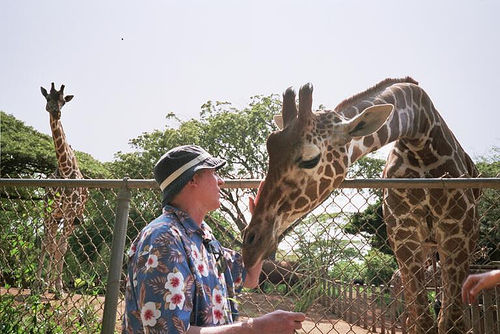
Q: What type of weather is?
A: It is clear.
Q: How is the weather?
A: It is clear.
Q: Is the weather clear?
A: Yes, it is clear.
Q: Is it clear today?
A: Yes, it is clear.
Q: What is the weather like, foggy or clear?
A: It is clear.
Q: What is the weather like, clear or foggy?
A: It is clear.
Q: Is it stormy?
A: No, it is clear.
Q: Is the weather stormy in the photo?
A: No, it is clear.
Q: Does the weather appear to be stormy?
A: No, it is clear.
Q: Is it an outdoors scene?
A: Yes, it is outdoors.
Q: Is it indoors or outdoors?
A: It is outdoors.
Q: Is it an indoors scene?
A: No, it is outdoors.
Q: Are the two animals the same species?
A: Yes, all the animals are giraffes.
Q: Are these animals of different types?
A: No, all the animals are giraffes.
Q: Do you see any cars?
A: No, there are no cars.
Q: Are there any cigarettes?
A: No, there are no cigarettes.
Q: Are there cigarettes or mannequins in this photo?
A: No, there are no cigarettes or mannequins.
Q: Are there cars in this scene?
A: No, there are no cars.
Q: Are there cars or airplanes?
A: No, there are no cars or airplanes.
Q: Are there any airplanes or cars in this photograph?
A: No, there are no cars or airplanes.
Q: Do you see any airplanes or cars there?
A: No, there are no cars or airplanes.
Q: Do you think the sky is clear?
A: Yes, the sky is clear.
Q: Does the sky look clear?
A: Yes, the sky is clear.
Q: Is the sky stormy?
A: No, the sky is clear.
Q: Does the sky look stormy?
A: No, the sky is clear.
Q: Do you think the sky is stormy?
A: No, the sky is clear.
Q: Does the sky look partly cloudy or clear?
A: The sky is clear.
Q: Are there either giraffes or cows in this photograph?
A: Yes, there is a giraffe.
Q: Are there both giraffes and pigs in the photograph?
A: No, there is a giraffe but no pigs.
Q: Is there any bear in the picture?
A: No, there are no bears.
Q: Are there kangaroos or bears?
A: No, there are no bears or kangaroos.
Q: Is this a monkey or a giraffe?
A: This is a giraffe.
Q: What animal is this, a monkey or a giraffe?
A: This is a giraffe.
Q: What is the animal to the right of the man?
A: The animal is a giraffe.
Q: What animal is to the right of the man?
A: The animal is a giraffe.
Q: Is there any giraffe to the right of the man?
A: Yes, there is a giraffe to the right of the man.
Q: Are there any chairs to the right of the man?
A: No, there is a giraffe to the right of the man.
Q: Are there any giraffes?
A: Yes, there is a giraffe.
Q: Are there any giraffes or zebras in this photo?
A: Yes, there is a giraffe.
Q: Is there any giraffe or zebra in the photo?
A: Yes, there is a giraffe.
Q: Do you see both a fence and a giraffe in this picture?
A: Yes, there are both a giraffe and a fence.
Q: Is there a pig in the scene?
A: No, there are no pigs.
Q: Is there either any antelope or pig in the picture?
A: No, there are no pigs or antelopes.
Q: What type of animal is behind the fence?
A: The animal is a giraffe.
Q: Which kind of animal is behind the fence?
A: The animal is a giraffe.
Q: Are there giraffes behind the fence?
A: Yes, there is a giraffe behind the fence.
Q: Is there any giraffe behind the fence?
A: Yes, there is a giraffe behind the fence.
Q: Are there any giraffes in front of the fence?
A: No, the giraffe is behind the fence.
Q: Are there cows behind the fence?
A: No, there is a giraffe behind the fence.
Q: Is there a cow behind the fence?
A: No, there is a giraffe behind the fence.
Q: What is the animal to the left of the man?
A: The animal is a giraffe.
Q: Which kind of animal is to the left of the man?
A: The animal is a giraffe.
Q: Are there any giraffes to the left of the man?
A: Yes, there is a giraffe to the left of the man.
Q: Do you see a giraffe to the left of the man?
A: Yes, there is a giraffe to the left of the man.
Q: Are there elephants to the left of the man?
A: No, there is a giraffe to the left of the man.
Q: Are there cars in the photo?
A: No, there are no cars.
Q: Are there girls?
A: No, there are no girls.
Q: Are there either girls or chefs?
A: No, there are no girls or chefs.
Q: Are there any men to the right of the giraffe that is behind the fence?
A: Yes, there is a man to the right of the giraffe.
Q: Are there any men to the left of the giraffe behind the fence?
A: No, the man is to the right of the giraffe.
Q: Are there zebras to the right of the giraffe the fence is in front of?
A: No, there is a man to the right of the giraffe.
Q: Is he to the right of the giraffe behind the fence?
A: Yes, the man is to the right of the giraffe.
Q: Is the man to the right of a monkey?
A: No, the man is to the right of the giraffe.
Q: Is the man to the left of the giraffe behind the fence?
A: No, the man is to the right of the giraffe.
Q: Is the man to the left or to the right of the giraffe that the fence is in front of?
A: The man is to the right of the giraffe.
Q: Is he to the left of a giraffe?
A: Yes, the man is to the left of a giraffe.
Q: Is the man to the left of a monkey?
A: No, the man is to the left of a giraffe.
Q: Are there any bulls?
A: No, there are no bulls.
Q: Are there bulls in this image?
A: No, there are no bulls.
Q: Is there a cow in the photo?
A: No, there are no cows.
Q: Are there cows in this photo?
A: No, there are no cows.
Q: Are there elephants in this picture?
A: No, there are no elephants.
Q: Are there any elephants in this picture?
A: No, there are no elephants.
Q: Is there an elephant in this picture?
A: No, there are no elephants.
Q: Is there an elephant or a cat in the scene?
A: No, there are no elephants or cats.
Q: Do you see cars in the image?
A: No, there are no cars.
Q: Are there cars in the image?
A: No, there are no cars.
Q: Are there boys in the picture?
A: No, there are no boys.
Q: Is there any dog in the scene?
A: No, there are no dogs.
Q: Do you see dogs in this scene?
A: No, there are no dogs.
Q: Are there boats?
A: No, there are no boats.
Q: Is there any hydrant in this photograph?
A: No, there are no fire hydrants.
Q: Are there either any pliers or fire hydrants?
A: No, there are no fire hydrants or pliers.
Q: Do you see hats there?
A: Yes, there is a hat.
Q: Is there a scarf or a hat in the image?
A: Yes, there is a hat.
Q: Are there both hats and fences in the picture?
A: Yes, there are both a hat and a fence.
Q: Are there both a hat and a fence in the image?
A: Yes, there are both a hat and a fence.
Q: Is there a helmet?
A: No, there are no helmets.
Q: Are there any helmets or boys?
A: No, there are no helmets or boys.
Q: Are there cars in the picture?
A: No, there are no cars.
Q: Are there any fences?
A: Yes, there is a fence.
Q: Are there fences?
A: Yes, there is a fence.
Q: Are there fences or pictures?
A: Yes, there is a fence.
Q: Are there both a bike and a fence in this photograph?
A: No, there is a fence but no bikes.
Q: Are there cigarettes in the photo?
A: No, there are no cigarettes.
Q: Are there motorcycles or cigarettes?
A: No, there are no cigarettes or motorcycles.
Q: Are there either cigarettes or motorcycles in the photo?
A: No, there are no cigarettes or motorcycles.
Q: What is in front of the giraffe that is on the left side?
A: The fence is in front of the giraffe.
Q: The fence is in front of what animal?
A: The fence is in front of the giraffe.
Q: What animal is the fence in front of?
A: The fence is in front of the giraffe.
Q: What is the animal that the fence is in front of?
A: The animal is a giraffe.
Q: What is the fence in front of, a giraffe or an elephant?
A: The fence is in front of a giraffe.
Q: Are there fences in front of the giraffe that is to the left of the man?
A: Yes, there is a fence in front of the giraffe.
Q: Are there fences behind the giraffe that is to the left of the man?
A: No, the fence is in front of the giraffe.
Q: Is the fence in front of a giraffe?
A: Yes, the fence is in front of a giraffe.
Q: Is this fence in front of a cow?
A: No, the fence is in front of a giraffe.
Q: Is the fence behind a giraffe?
A: No, the fence is in front of a giraffe.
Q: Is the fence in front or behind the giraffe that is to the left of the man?
A: The fence is in front of the giraffe.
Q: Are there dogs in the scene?
A: No, there are no dogs.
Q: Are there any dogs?
A: No, there are no dogs.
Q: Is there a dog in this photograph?
A: No, there are no dogs.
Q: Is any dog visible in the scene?
A: No, there are no dogs.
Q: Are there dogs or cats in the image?
A: No, there are no dogs or cats.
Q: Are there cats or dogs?
A: No, there are no dogs or cats.